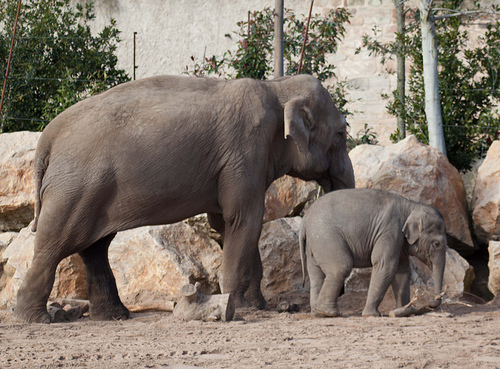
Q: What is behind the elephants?
A: Large rocks.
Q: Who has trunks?
A: Elephants.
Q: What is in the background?
A: Trees.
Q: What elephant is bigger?
A: Elephant on the left.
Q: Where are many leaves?
A: On trees.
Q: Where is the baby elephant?
A: On the right.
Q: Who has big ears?
A: The elephants.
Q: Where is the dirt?
A: On the ground.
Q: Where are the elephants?
A: In a zoo.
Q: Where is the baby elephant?
A: Next to the adult elephant.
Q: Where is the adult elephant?
A: Next to the baby elephant.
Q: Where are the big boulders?
A: Behind the elephants.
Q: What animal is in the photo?
A: Elephant.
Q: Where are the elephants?
A: In a zoo.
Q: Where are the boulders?
A: Behind the elephants.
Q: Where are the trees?
A: Behind the boulders.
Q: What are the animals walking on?
A: Dirt.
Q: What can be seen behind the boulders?
A: Trees.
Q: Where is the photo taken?
A: Outdoors at the zoo.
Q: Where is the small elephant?
A: In front of the large elephant.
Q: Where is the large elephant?
A: Behind the small elephant.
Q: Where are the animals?
A: Beside rocks.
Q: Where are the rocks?
A: In dirt.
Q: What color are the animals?
A: Gray.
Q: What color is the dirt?
A: Brown.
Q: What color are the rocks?
A: Tan.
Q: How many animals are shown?
A: Two.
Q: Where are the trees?
A: Behind rocks.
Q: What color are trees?
A: Green.